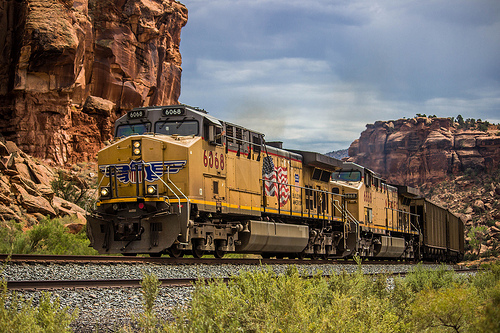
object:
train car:
[332, 162, 420, 265]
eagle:
[98, 160, 186, 184]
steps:
[325, 193, 362, 261]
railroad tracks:
[1, 243, 500, 332]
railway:
[65, 254, 100, 266]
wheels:
[120, 247, 305, 262]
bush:
[3, 264, 499, 332]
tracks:
[0, 249, 491, 285]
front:
[81, 103, 200, 255]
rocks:
[168, 293, 173, 299]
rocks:
[138, 292, 145, 302]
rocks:
[91, 287, 95, 299]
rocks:
[85, 310, 97, 315]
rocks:
[63, 293, 76, 300]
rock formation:
[339, 115, 500, 269]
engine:
[83, 102, 243, 257]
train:
[88, 90, 474, 302]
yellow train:
[82, 105, 424, 260]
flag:
[263, 155, 291, 207]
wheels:
[122, 213, 231, 259]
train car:
[92, 103, 337, 260]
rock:
[0, 0, 200, 245]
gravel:
[118, 263, 249, 279]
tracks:
[19, 242, 263, 293]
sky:
[171, 0, 498, 150]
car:
[421, 193, 466, 262]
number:
[203, 149, 224, 170]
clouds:
[209, 6, 294, 36]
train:
[85, 102, 465, 263]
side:
[266, 169, 387, 218]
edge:
[44, 275, 84, 296]